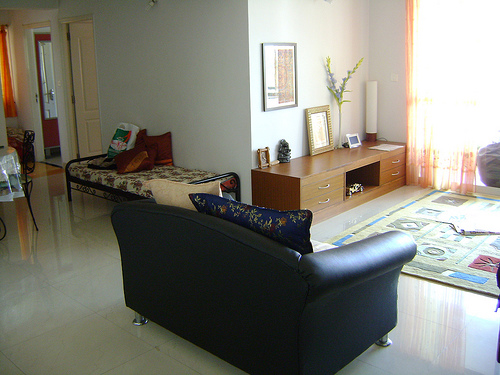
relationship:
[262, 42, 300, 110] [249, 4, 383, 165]
mirror on top of wall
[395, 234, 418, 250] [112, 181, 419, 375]
light on top of leather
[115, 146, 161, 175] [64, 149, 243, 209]
pillow on top of bench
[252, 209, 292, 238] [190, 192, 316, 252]
pattern on pillow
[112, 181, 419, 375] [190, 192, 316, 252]
sofa with pillow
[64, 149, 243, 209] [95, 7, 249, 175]
daybed near wall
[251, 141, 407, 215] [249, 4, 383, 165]
table near wall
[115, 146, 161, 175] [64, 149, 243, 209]
pillow on bed